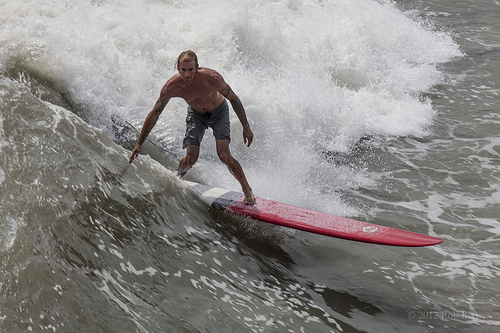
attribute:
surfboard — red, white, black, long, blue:
[179, 178, 443, 256]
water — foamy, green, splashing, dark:
[1, 1, 498, 331]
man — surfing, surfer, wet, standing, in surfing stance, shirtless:
[128, 44, 266, 208]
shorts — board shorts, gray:
[178, 103, 232, 146]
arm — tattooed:
[211, 70, 262, 144]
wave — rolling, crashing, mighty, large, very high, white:
[11, 3, 463, 206]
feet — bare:
[171, 171, 261, 205]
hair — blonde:
[177, 48, 199, 65]